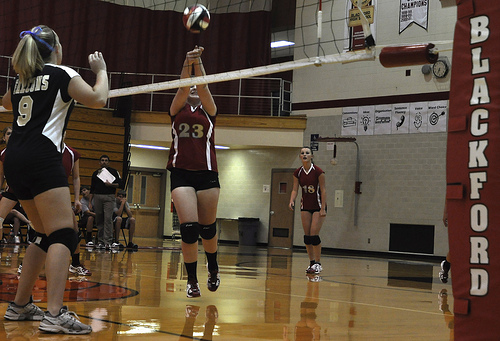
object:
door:
[135, 174, 161, 238]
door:
[118, 172, 135, 247]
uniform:
[2, 63, 81, 201]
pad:
[46, 227, 80, 254]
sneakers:
[184, 262, 221, 298]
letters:
[466, 14, 491, 296]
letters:
[13, 74, 51, 94]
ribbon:
[20, 26, 55, 51]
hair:
[10, 25, 56, 86]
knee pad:
[303, 234, 321, 246]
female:
[289, 146, 329, 274]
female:
[167, 45, 221, 298]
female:
[0, 24, 109, 336]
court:
[0, 233, 500, 341]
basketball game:
[0, 3, 328, 334]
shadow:
[177, 303, 219, 341]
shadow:
[282, 280, 322, 341]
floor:
[0, 246, 497, 341]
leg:
[310, 210, 327, 263]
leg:
[196, 188, 221, 263]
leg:
[170, 186, 200, 277]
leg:
[31, 187, 78, 310]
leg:
[103, 201, 115, 242]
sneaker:
[308, 264, 323, 274]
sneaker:
[37, 305, 93, 335]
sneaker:
[2, 294, 46, 322]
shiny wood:
[0, 237, 457, 339]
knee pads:
[180, 219, 218, 244]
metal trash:
[237, 216, 260, 247]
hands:
[185, 46, 204, 62]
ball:
[182, 4, 210, 34]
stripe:
[204, 109, 214, 171]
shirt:
[166, 102, 219, 173]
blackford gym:
[0, 0, 500, 341]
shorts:
[301, 209, 328, 213]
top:
[292, 162, 328, 209]